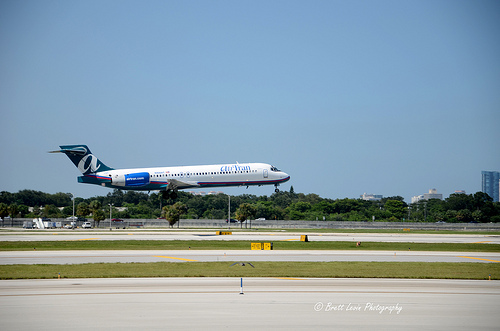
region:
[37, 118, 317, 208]
Airplane taking off into the air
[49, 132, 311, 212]
Blue and white airplane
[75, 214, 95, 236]
White vehicle parked on the runway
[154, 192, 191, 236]
Group of trees with green leaves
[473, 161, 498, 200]
Large metal skyscraper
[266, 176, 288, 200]
Rubber and metal airplane landing gear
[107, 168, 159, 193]
blue and white airplane engine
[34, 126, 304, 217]
Airplane in the air above the runway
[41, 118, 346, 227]
Airplane taking off into the sky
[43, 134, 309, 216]
passenger airplane taking off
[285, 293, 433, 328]
White letters for a photography studio.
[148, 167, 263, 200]
A row of windows on a plane.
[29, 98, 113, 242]
The tail of a plane.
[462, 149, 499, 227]
A tall gray building.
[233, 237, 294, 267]
Yellow traffic squares on grass.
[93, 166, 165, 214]
Blue and white engine of plane.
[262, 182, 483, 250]
A group of green trees.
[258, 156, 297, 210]
The pilots window on plane.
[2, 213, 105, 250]
Cars in a parking lot.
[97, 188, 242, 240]
Two tall silver poles.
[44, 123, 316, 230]
A airplane is taking off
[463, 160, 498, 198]
Building is in the background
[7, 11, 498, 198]
The sky is clear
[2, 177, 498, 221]
Trees are in the background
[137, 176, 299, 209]
Airplane's wheels are in view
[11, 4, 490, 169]
The sky is light blue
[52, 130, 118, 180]
The tail of the plane has the letter "a"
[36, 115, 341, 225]
Side view of a airplane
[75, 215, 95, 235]
A Car is in the background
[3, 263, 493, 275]
Grass is in the foreground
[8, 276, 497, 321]
empty airport runway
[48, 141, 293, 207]
white and blue plane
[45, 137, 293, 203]
commercial plane taking flight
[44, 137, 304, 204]
large plane with airTran logo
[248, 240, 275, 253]
yellow guiding component on ground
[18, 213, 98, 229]
various vehicles in background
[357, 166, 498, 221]
sky scrapers behind trees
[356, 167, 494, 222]
city in background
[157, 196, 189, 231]
three trees at airport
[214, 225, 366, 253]
airport traffic control aids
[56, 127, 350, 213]
Small air liner in flight.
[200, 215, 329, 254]
Yellow and black distance markers.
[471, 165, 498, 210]
Large blue office building.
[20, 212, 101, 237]
Several cars in a parking lot.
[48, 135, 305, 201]
Airplane painted white, red, and blue.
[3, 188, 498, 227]
Line of large trees.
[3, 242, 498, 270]
Concrete runway with yellow markings.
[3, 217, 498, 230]
Long metal fence.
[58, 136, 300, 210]
Airplane with landing gear out.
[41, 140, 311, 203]
Small commercial airliner.